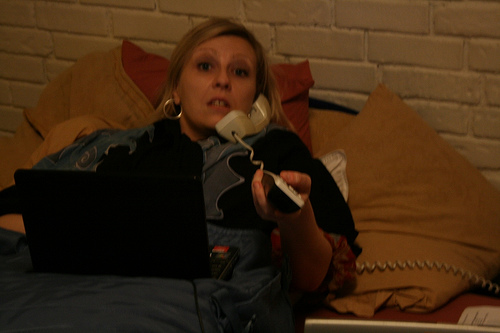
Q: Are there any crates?
A: No, there are no crates.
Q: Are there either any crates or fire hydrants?
A: No, there are no crates or fire hydrants.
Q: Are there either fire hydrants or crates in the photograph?
A: No, there are no crates or fire hydrants.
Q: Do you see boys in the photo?
A: No, there are no boys.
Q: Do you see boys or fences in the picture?
A: No, there are no boys or fences.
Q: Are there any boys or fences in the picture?
A: No, there are no boys or fences.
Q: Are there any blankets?
A: Yes, there is a blanket.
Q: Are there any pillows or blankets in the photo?
A: Yes, there is a blanket.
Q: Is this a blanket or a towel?
A: This is a blanket.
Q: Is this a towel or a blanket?
A: This is a blanket.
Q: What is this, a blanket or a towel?
A: This is a blanket.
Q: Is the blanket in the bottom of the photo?
A: Yes, the blanket is in the bottom of the image.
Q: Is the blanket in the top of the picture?
A: No, the blanket is in the bottom of the image.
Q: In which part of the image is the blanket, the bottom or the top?
A: The blanket is in the bottom of the image.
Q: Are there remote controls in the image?
A: Yes, there is a remote control.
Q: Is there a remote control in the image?
A: Yes, there is a remote control.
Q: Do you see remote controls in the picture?
A: Yes, there is a remote control.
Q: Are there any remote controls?
A: Yes, there is a remote control.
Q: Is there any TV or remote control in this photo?
A: Yes, there is a remote control.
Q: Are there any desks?
A: No, there are no desks.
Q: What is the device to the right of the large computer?
A: The device is a remote control.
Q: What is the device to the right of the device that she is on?
A: The device is a remote control.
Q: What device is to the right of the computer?
A: The device is a remote control.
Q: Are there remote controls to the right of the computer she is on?
A: Yes, there is a remote control to the right of the computer.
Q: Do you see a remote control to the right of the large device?
A: Yes, there is a remote control to the right of the computer.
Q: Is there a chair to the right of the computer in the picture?
A: No, there is a remote control to the right of the computer.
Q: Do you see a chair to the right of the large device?
A: No, there is a remote control to the right of the computer.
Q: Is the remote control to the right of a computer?
A: Yes, the remote control is to the right of a computer.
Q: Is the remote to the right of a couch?
A: No, the remote is to the right of a computer.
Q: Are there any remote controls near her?
A: Yes, there is a remote control near the woman.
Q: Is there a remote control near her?
A: Yes, there is a remote control near the woman.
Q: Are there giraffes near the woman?
A: No, there is a remote control near the woman.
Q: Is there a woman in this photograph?
A: Yes, there is a woman.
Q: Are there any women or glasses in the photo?
A: Yes, there is a woman.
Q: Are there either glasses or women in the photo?
A: Yes, there is a woman.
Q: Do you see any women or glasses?
A: Yes, there is a woman.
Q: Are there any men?
A: No, there are no men.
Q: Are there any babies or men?
A: No, there are no men or babies.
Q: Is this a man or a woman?
A: This is a woman.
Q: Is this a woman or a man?
A: This is a woman.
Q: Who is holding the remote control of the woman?
A: The woman is holding the remote control.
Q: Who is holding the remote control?
A: The woman is holding the remote control.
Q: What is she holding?
A: The woman is holding the remote control.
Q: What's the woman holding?
A: The woman is holding the remote control.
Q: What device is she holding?
A: The woman is holding the remote.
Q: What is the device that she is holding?
A: The device is a remote control.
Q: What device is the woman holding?
A: The woman is holding the remote.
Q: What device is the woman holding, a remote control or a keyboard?
A: The woman is holding a remote control.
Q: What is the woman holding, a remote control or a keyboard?
A: The woman is holding a remote control.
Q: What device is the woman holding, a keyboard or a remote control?
A: The woman is holding a remote control.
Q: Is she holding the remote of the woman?
A: Yes, the woman is holding the remote control.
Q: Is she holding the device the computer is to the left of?
A: Yes, the woman is holding the remote control.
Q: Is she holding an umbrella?
A: No, the woman is holding the remote control.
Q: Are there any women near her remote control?
A: Yes, there is a woman near the remote control.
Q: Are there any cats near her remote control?
A: No, there is a woman near the remote control.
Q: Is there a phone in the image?
A: Yes, there is a phone.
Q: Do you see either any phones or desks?
A: Yes, there is a phone.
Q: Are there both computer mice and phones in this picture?
A: No, there is a phone but no computer mice.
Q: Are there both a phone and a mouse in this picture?
A: No, there is a phone but no computer mice.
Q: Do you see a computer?
A: Yes, there is a computer.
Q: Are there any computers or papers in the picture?
A: Yes, there is a computer.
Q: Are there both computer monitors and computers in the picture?
A: No, there is a computer but no computer monitors.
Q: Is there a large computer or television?
A: Yes, there is a large computer.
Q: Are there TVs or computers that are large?
A: Yes, the computer is large.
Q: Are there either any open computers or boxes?
A: Yes, there is an open computer.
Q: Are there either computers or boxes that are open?
A: Yes, the computer is open.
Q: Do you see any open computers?
A: Yes, there is an open computer.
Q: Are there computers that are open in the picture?
A: Yes, there is an open computer.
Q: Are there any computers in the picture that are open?
A: Yes, there is a computer that is open.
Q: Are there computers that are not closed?
A: Yes, there is a open computer.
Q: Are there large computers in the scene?
A: Yes, there is a large computer.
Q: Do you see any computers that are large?
A: Yes, there is a large computer.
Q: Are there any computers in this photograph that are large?
A: Yes, there is a computer that is large.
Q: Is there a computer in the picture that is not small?
A: Yes, there is a large computer.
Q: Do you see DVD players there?
A: No, there are no DVD players.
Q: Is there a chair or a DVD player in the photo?
A: No, there are no DVD players or chairs.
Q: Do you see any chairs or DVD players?
A: No, there are no DVD players or chairs.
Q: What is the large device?
A: The device is a computer.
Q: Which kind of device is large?
A: The device is a computer.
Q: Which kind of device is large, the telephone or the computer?
A: The computer is large.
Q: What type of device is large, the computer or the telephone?
A: The computer is large.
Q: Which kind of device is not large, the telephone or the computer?
A: The telephone is not large.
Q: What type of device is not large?
A: The device is a phone.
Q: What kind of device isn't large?
A: The device is a phone.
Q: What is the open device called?
A: The device is a computer.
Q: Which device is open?
A: The device is a computer.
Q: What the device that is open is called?
A: The device is a computer.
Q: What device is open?
A: The device is a computer.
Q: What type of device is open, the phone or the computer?
A: The computer is open.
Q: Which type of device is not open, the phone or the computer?
A: The phone is not open.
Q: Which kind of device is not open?
A: The device is a phone.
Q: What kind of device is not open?
A: The device is a phone.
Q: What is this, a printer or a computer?
A: This is a computer.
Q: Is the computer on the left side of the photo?
A: Yes, the computer is on the left of the image.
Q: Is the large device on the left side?
A: Yes, the computer is on the left of the image.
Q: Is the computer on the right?
A: No, the computer is on the left of the image.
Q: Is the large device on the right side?
A: No, the computer is on the left of the image.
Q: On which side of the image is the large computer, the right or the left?
A: The computer is on the left of the image.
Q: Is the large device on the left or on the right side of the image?
A: The computer is on the left of the image.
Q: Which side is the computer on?
A: The computer is on the left of the image.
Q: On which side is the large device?
A: The computer is on the left of the image.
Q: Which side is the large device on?
A: The computer is on the left of the image.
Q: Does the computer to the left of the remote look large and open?
A: Yes, the computer is large and open.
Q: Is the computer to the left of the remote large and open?
A: Yes, the computer is large and open.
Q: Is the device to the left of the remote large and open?
A: Yes, the computer is large and open.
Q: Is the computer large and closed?
A: No, the computer is large but open.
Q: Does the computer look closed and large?
A: No, the computer is large but open.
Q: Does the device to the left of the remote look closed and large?
A: No, the computer is large but open.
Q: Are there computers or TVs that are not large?
A: No, there is a computer but it is large.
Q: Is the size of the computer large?
A: Yes, the computer is large.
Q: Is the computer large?
A: Yes, the computer is large.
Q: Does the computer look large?
A: Yes, the computer is large.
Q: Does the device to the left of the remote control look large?
A: Yes, the computer is large.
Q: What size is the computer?
A: The computer is large.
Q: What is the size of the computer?
A: The computer is large.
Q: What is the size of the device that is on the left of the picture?
A: The computer is large.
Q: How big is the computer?
A: The computer is large.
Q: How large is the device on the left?
A: The computer is large.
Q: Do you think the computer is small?
A: No, the computer is large.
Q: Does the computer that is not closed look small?
A: No, the computer is large.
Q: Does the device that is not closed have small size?
A: No, the computer is large.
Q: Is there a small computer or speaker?
A: No, there is a computer but it is large.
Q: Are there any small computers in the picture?
A: No, there is a computer but it is large.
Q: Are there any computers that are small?
A: No, there is a computer but it is large.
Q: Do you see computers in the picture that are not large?
A: No, there is a computer but it is large.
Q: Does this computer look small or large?
A: The computer is large.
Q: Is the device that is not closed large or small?
A: The computer is large.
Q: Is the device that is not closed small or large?
A: The computer is large.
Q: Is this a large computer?
A: Yes, this is a large computer.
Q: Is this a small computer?
A: No, this is a large computer.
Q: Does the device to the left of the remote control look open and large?
A: Yes, the computer is open and large.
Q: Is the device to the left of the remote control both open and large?
A: Yes, the computer is open and large.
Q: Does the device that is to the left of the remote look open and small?
A: No, the computer is open but large.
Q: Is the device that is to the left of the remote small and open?
A: No, the computer is open but large.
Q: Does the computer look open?
A: Yes, the computer is open.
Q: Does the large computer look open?
A: Yes, the computer is open.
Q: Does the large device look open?
A: Yes, the computer is open.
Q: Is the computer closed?
A: No, the computer is open.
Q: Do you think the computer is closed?
A: No, the computer is open.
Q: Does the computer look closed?
A: No, the computer is open.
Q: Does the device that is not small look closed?
A: No, the computer is open.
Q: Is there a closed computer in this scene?
A: No, there is a computer but it is open.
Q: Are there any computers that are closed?
A: No, there is a computer but it is open.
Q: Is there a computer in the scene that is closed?
A: No, there is a computer but it is open.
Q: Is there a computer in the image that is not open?
A: No, there is a computer but it is open.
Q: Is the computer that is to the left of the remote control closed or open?
A: The computer is open.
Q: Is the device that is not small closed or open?
A: The computer is open.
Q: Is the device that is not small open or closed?
A: The computer is open.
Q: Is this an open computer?
A: Yes, this is an open computer.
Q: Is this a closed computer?
A: No, this is an open computer.